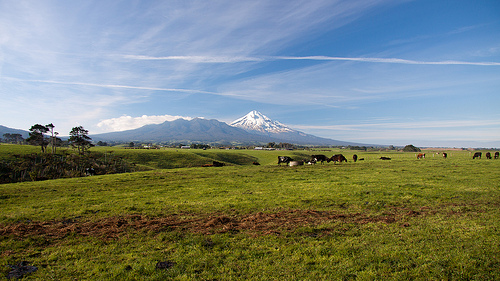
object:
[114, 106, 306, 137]
mountain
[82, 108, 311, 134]
mountain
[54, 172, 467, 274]
landscape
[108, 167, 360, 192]
grass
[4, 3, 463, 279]
photo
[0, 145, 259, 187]
hill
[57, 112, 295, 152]
mountain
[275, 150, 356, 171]
cows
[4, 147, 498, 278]
grass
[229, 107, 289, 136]
snow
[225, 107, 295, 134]
mountain top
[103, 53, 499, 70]
line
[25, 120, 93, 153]
trees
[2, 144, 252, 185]
hill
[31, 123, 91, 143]
leaves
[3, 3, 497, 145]
clouds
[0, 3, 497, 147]
sky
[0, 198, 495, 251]
grass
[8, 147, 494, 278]
field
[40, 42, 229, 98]
cloud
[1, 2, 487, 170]
sky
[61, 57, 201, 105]
cloud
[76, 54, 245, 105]
cloud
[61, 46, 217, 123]
cloud